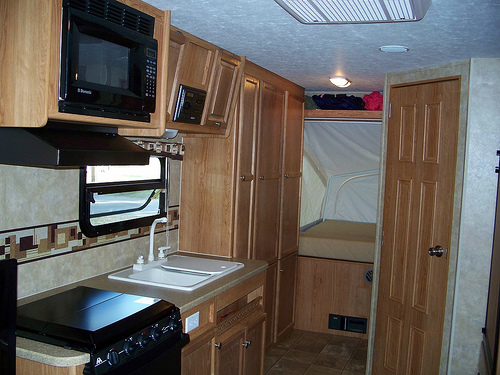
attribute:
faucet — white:
[147, 213, 174, 258]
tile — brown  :
[286, 324, 363, 366]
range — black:
[17, 282, 191, 374]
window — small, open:
[75, 153, 167, 235]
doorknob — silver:
[424, 236, 443, 258]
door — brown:
[354, 71, 466, 373]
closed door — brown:
[369, 78, 463, 371]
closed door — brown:
[237, 82, 260, 257]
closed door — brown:
[257, 79, 284, 258]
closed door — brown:
[281, 83, 303, 330]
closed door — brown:
[245, 318, 265, 371]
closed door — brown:
[208, 330, 244, 372]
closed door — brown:
[207, 57, 240, 122]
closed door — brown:
[171, 46, 219, 115]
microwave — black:
[62, 16, 159, 114]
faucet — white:
[134, 216, 174, 268]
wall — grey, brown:
[2, 125, 179, 255]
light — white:
[302, 52, 373, 125]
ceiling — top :
[245, 23, 342, 66]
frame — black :
[77, 150, 168, 238]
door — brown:
[365, 87, 497, 352]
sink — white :
[122, 248, 229, 298]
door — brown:
[364, 73, 458, 373]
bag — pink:
[343, 77, 394, 130]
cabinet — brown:
[234, 74, 254, 256]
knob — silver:
[412, 235, 457, 275]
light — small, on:
[327, 72, 351, 89]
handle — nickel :
[424, 242, 450, 259]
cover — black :
[83, 166, 174, 226]